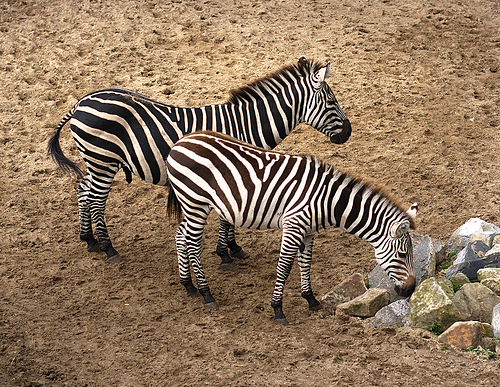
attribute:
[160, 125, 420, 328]
zebra — brown, white, black and white, black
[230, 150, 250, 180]
black — white, light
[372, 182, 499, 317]
rocks — black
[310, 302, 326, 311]
hoof — black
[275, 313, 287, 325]
hoof — black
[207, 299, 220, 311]
hoof — black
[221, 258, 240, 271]
hoof — black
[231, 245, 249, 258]
hoof — black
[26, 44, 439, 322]
zebras — white, brown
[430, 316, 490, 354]
rock — black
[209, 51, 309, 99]
zebra mane — striped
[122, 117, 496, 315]
zebra — black and white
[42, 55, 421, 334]
zebras — black and white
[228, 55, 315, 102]
mane — stiff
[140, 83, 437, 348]
zebra — striped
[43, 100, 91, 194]
tail — black, white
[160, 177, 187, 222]
tail — white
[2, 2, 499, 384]
ground — brown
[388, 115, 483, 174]
clay — black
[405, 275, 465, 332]
rock — black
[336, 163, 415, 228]
mane — stiff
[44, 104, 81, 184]
tail — striped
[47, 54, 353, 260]
zebra — white, brown, black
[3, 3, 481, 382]
dirt — brown